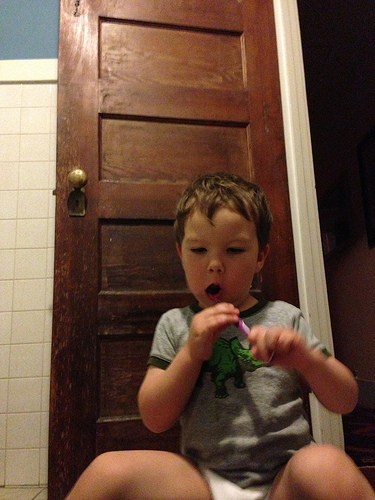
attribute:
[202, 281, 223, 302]
mouth — open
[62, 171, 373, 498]
kid — little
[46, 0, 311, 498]
door — wooden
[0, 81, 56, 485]
tile — white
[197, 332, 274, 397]
dinosaur — green